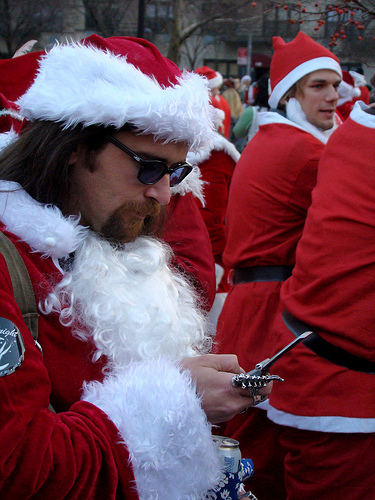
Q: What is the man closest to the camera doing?
A: Looking at his phone.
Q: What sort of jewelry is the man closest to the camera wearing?
A: Ring.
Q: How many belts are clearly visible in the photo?
A: Two.